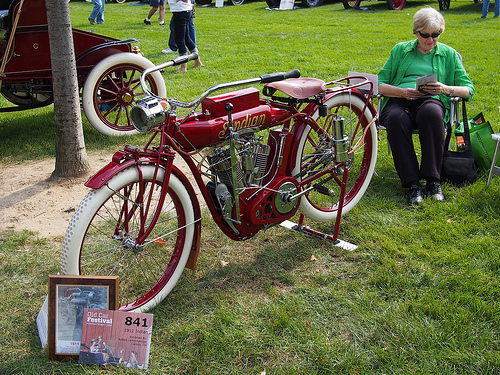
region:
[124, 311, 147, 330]
the number 841 in black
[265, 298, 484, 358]
grass in the field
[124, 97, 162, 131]
the motorbike headlight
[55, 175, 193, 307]
the bike tire is white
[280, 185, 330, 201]
the pedal of the bike is black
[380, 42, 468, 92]
this cloth is green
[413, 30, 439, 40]
black sunglasses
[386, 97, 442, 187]
a brown pant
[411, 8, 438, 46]
the heasd of the woman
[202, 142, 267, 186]
the motor of the bike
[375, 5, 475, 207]
A woman siting on a folding chair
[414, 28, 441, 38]
A pair of dark sunglases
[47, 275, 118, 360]
A framed picture of a bicycle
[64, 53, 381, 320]
An antique red motorcycle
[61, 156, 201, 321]
The white tire of a motorcycle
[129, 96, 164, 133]
The chromed headlight of a motorcycle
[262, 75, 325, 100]
The red seat of an old motorcycle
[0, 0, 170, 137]
Part of a very old car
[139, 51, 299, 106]
The handle bars of an old motorcycle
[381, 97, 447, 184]
A black pair of pants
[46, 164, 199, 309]
tire on the bike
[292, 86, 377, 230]
tire on the bike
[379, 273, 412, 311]
patch of green grass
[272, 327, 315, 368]
patch of green grass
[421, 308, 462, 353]
patch of green grass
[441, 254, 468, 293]
patch of green grass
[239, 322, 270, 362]
patch of green grass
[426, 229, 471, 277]
patch of green grass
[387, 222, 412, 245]
patch of green grass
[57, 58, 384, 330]
Red and white bicycle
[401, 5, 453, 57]
A lady wearing sunglasses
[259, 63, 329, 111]
Red bicycle seat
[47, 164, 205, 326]
Red and white bicycle tire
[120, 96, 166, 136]
Silver headlight on a bicycle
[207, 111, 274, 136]
Gold writing on a bicycle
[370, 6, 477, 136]
A lady reading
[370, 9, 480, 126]
A lady wearing a green shirt and t-shirt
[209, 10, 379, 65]
Green glass on a field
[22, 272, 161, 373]
A book and frame placed on grass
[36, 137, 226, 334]
FRONT TIRE ON THE BIKE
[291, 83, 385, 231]
REAR TIRE ON THE BIKE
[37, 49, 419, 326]
OLD RED INDIAN BIKE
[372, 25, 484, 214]
WOMAN SITTING IN A CHAIR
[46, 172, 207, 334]
THE TIRE IS WHITE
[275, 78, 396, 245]
THE TIRE RIM IS RED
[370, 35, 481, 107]
WOMAN WEARING GREEN SHIRT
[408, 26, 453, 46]
WOMAN WEARING SUNGLASSES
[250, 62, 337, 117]
THE BIKE SEAT IS RED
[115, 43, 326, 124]
THE BIKE HAS LONG HANDLEBARS